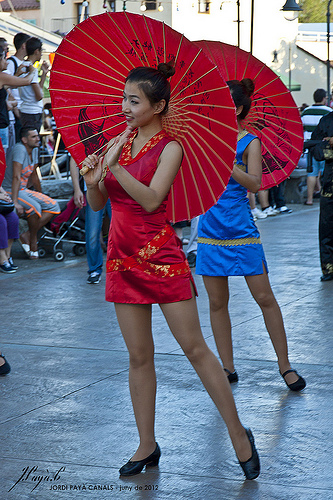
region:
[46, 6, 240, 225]
umbrella in woman's hands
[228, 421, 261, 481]
black slipper on left foot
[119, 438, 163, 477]
black slipper on right foot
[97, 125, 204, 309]
red dress on woman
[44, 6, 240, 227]
large umbrella behind woman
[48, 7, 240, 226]
large umbrella is red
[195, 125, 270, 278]
second woman wearing blue dress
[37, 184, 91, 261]
small stroller against bench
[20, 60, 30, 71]
man holding white camera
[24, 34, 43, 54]
onlooker has black hair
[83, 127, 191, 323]
the dress is red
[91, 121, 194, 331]
the dress is red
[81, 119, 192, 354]
the dress is red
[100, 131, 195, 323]
the dress is red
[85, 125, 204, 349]
the dress is red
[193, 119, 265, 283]
the dress is blue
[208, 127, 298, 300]
the dress is blue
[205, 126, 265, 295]
the dress is blue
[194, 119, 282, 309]
the dress is blue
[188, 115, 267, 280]
the dress is blue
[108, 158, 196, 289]
The dress is red.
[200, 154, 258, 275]
The dress is blue.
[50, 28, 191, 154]
The umbrella is red.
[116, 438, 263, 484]
The woman is wearing black shoes.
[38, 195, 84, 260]
A stroller on the side.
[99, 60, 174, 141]
The woman is Asian.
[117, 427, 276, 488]
the shoes are black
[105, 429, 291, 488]
the shoes are black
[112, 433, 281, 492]
the shoes are black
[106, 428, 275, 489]
the shoes are black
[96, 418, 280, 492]
the shoes are black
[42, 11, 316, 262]
the umbrellas are red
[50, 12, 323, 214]
the umbrellas are red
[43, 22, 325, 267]
the umbrellas are red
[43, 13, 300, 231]
the umbrellas are red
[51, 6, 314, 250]
the umbrellas are red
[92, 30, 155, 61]
A red umbrella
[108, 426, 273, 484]
black shoes on the legs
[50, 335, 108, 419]
A paved floor in the photo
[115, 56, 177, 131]
Head of a woman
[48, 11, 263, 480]
a woman holding an umbrella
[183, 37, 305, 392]
a woman holding an umbrella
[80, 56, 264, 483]
a woman wearing a red dress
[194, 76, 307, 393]
a woman wearing a blue dress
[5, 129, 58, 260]
a guy wearing orange and grey shorts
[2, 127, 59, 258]
a guy wearing an orange and grey shirt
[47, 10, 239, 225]
a large red umbrella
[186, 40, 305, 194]
a large red umbrella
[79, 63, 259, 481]
a woman wearing black shoes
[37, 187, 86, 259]
a silver and red baby carriage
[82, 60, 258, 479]
lady is holding umbrella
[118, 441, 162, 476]
shoe is on the ground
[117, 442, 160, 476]
shoe is black